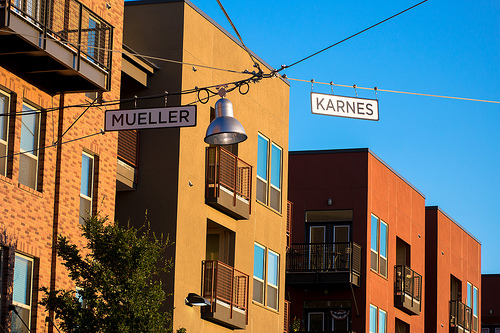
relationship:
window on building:
[76, 144, 98, 234] [0, 1, 290, 332]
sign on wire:
[101, 104, 198, 131] [1, 2, 435, 118]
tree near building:
[39, 210, 188, 333] [0, 1, 290, 332]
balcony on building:
[201, 257, 250, 331] [0, 1, 290, 332]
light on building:
[185, 290, 210, 309] [0, 1, 290, 332]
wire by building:
[1, 2, 435, 118] [0, 1, 290, 332]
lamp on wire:
[203, 97, 250, 148] [1, 2, 435, 118]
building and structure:
[0, 1, 290, 332] [287, 148, 483, 332]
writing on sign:
[114, 109, 189, 124] [101, 104, 198, 131]